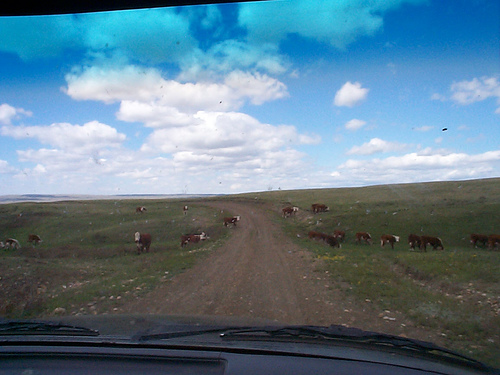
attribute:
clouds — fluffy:
[2, 66, 317, 179]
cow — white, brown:
[132, 228, 153, 253]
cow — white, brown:
[223, 214, 242, 228]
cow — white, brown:
[281, 202, 300, 217]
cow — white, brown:
[134, 205, 146, 214]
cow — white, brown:
[378, 231, 401, 249]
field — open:
[2, 171, 499, 352]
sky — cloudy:
[146, 115, 279, 189]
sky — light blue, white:
[2, 0, 499, 189]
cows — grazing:
[117, 204, 247, 269]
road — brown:
[247, 213, 327, 343]